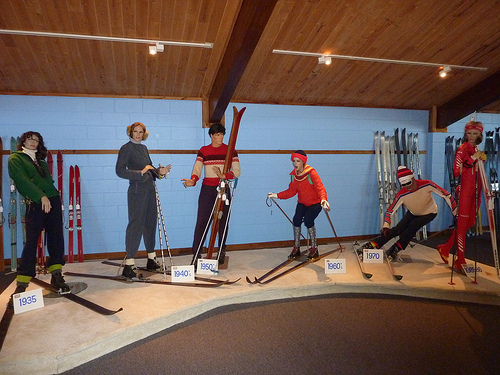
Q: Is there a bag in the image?
A: No, there are no bags.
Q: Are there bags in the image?
A: No, there are no bags.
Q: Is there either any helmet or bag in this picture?
A: No, there are no bags or helmets.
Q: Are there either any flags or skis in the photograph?
A: Yes, there are skis.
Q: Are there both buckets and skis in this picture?
A: No, there are skis but no buckets.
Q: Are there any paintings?
A: No, there are no paintings.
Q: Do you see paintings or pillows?
A: No, there are no paintings or pillows.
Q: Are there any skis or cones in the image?
A: Yes, there are skis.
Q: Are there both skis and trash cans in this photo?
A: No, there are skis but no trash cans.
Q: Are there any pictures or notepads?
A: No, there are no pictures or notepads.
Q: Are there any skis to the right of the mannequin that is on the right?
A: Yes, there are skis to the right of the mannequin.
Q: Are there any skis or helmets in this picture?
A: Yes, there are skis.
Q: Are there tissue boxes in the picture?
A: No, there are no tissue boxes.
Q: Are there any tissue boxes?
A: No, there are no tissue boxes.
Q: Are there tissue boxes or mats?
A: No, there are no tissue boxes or mats.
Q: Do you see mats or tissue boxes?
A: No, there are no tissue boxes or mats.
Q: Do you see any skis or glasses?
A: Yes, there are skis.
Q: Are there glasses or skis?
A: Yes, there are skis.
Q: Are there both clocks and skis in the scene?
A: No, there are skis but no clocks.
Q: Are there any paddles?
A: No, there are no paddles.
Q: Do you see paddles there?
A: No, there are no paddles.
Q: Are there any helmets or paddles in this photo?
A: No, there are no paddles or helmets.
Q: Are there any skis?
A: Yes, there are skis.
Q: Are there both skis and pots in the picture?
A: No, there are skis but no pots.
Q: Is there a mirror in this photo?
A: No, there are no mirrors.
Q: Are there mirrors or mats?
A: No, there are no mirrors or mats.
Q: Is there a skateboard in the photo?
A: No, there are no skateboards.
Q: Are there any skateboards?
A: No, there are no skateboards.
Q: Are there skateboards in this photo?
A: No, there are no skateboards.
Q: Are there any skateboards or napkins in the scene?
A: No, there are no skateboards or napkins.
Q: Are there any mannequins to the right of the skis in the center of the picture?
A: Yes, there is a mannequin to the right of the skis.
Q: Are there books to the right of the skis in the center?
A: No, there is a mannequin to the right of the skis.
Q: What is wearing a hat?
A: The mannequin is wearing a hat.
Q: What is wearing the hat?
A: The mannequin is wearing a hat.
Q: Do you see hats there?
A: Yes, there is a hat.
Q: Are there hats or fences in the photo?
A: Yes, there is a hat.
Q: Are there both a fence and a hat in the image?
A: No, there is a hat but no fences.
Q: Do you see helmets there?
A: No, there are no helmets.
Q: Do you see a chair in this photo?
A: No, there are no chairs.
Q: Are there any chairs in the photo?
A: No, there are no chairs.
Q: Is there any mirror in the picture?
A: No, there are no mirrors.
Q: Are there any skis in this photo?
A: Yes, there are skis.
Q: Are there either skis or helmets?
A: Yes, there are skis.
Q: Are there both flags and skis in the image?
A: No, there are skis but no flags.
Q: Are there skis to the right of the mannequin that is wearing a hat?
A: Yes, there are skis to the right of the mannequin.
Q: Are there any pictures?
A: No, there are no pictures.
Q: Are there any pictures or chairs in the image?
A: No, there are no pictures or chairs.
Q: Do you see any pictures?
A: No, there are no pictures.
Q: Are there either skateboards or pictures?
A: No, there are no pictures or skateboards.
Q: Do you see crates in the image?
A: No, there are no crates.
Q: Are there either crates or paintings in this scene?
A: No, there are no crates or paintings.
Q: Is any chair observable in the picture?
A: No, there are no chairs.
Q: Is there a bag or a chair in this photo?
A: No, there are no chairs or bags.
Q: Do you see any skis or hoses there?
A: Yes, there are skis.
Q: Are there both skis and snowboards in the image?
A: No, there are skis but no snowboards.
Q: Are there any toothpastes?
A: No, there are no toothpastes.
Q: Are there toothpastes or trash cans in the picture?
A: No, there are no toothpastes or trash cans.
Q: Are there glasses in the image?
A: No, there are no glasses.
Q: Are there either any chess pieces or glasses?
A: No, there are no glasses or chess pieces.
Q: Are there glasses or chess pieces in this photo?
A: No, there are no glasses or chess pieces.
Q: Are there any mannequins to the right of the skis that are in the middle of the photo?
A: Yes, there is a mannequin to the right of the skis.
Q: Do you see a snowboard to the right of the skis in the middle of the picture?
A: No, there is a mannequin to the right of the skis.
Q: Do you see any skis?
A: Yes, there are skis.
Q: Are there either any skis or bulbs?
A: Yes, there are skis.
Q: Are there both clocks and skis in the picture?
A: No, there are skis but no clocks.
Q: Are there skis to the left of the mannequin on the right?
A: Yes, there are skis to the left of the mannequin.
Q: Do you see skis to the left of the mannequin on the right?
A: Yes, there are skis to the left of the mannequin.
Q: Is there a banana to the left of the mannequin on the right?
A: No, there are skis to the left of the mannequin.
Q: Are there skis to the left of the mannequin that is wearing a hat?
A: Yes, there are skis to the left of the mannequin.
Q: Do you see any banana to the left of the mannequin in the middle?
A: No, there are skis to the left of the mannequin.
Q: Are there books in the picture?
A: No, there are no books.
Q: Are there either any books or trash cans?
A: No, there are no books or trash cans.